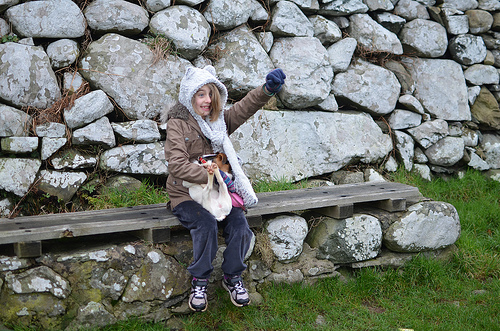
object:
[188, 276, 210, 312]
shoes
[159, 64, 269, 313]
girl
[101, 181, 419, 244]
bench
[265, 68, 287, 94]
glove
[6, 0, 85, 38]
rocks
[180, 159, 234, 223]
animal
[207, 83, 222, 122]
hair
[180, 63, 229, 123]
hat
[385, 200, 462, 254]
rocks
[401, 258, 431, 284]
grass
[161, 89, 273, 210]
coat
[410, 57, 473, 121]
rocks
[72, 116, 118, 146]
rocks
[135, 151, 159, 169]
dark grey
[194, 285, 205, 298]
laces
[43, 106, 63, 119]
grass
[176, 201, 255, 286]
pants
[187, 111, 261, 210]
scarf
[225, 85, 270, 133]
arm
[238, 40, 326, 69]
air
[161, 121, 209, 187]
sleeves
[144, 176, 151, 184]
blades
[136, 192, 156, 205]
grass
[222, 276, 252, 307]
sneakers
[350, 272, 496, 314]
ground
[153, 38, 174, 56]
grass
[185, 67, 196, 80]
ears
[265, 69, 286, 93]
hand